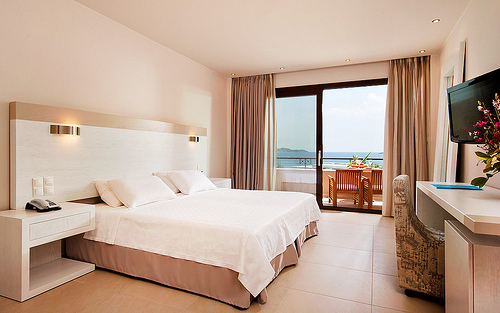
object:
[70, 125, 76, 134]
lights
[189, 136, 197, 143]
lights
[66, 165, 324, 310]
bed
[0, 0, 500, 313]
hotel room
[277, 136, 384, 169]
water view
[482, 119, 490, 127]
flowers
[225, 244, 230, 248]
sheets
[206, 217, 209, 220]
sheets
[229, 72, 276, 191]
curtain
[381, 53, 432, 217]
curtain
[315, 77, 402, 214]
door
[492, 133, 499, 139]
flowers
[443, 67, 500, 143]
television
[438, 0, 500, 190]
wall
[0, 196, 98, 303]
nightstand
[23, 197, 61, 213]
phone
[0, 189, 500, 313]
ground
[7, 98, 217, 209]
headboard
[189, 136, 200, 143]
light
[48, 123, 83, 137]
light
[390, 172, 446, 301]
chair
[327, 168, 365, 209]
side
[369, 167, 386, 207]
side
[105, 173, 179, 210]
pillow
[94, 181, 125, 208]
pillow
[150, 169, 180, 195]
pillow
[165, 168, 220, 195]
pillow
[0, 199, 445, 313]
floor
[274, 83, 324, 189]
doors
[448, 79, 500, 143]
tv screen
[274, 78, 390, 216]
window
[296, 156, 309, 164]
water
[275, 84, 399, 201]
patio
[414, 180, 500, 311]
desk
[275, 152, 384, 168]
ocean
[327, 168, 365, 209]
chair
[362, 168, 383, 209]
chair